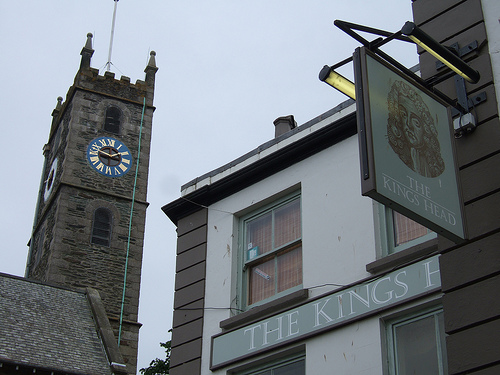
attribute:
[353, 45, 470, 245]
big sign — large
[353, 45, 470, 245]
sign — silver, large, big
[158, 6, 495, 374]
building — established, business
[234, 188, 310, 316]
window — large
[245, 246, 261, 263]
label — blue, white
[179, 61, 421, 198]
gray edge — white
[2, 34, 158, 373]
building — gray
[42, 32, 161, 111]
spirals — pointed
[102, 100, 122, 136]
window — curved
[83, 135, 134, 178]
clock — roman, big, blue, large, round, yellow, white, inside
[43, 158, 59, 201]
clock — white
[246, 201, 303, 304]
blinds — closed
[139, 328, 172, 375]
leaves — green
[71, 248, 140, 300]
bricks — gray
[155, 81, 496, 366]
part of the wall — white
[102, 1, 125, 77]
pole — white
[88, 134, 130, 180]
roman numerals — white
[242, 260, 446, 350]
words — large, white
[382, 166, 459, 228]
words — large, white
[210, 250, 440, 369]
sign — large